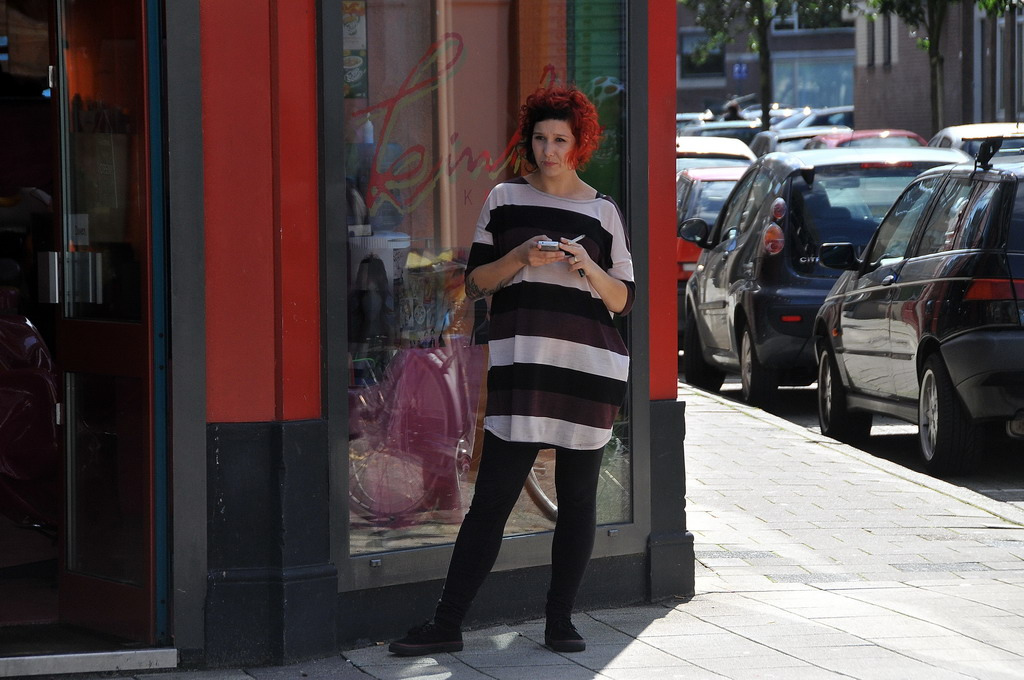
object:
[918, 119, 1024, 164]
cars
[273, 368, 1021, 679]
sidewalk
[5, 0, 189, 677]
door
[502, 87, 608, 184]
hair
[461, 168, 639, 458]
shirt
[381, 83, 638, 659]
woman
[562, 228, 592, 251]
cigarette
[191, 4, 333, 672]
building exterior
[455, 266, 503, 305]
tattoo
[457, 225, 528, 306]
arm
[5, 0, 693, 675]
building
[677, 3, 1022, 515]
street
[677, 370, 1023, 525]
curb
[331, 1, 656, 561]
window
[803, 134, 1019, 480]
car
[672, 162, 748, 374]
car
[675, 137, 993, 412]
car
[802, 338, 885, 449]
tire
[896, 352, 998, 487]
tire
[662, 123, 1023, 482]
row